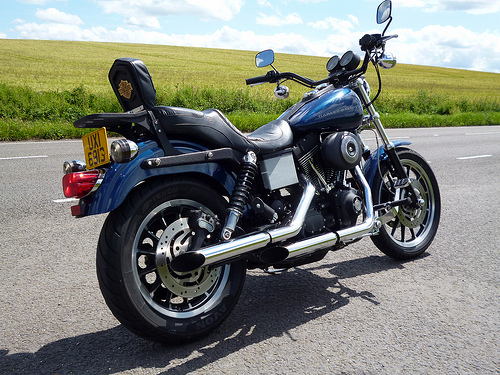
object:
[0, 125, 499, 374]
road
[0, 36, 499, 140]
grass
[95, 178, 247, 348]
wheel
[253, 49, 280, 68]
mirror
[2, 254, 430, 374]
shadow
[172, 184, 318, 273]
pipe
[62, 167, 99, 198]
light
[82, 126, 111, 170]
plate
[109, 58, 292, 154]
seat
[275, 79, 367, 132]
tank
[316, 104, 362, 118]
logo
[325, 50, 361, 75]
gauges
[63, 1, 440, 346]
bike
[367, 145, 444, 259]
tire